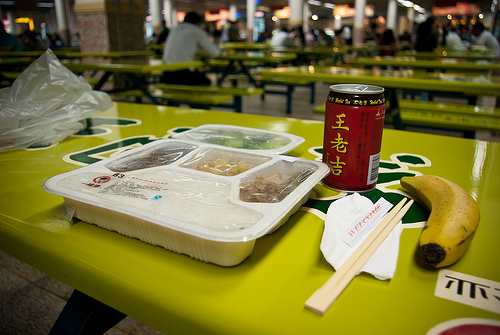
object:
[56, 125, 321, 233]
dinner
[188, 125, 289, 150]
side dish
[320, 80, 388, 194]
beverage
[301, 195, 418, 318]
chopsticks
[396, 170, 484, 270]
banana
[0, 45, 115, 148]
bag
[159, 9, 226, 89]
man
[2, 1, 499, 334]
food court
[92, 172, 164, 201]
heating instructions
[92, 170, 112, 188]
warning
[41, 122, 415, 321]
package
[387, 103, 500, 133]
bench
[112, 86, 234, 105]
bench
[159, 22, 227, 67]
shirt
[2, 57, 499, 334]
floor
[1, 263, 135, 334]
tile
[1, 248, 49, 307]
tile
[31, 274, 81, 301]
tile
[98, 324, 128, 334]
tile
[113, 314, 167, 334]
tile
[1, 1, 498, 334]
scene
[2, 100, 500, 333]
cafeteria table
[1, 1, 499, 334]
cafeteria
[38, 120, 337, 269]
container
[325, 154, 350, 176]
chinese characters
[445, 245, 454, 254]
brown speck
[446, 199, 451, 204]
brown speck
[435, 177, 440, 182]
brown speck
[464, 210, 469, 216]
brown speck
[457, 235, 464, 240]
brown speck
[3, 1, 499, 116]
background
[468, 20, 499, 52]
man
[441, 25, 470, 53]
man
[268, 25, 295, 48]
man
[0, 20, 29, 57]
man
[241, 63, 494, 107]
table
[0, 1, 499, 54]
group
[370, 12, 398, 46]
person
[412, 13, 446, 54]
person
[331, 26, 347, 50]
person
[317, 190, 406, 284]
napkin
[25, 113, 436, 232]
green writing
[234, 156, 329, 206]
compartment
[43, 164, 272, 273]
compartment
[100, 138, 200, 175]
compartment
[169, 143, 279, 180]
compartment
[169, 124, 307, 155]
compartment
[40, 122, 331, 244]
plastic